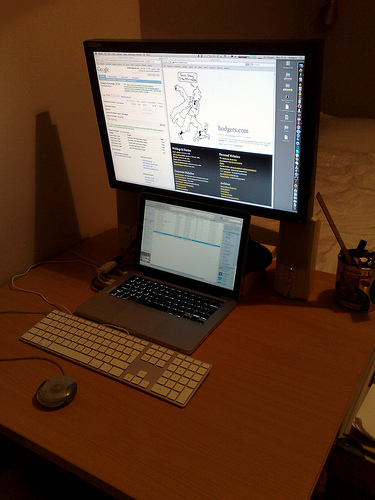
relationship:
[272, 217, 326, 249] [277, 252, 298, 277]
speaker with light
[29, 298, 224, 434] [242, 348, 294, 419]
flat keyboard desk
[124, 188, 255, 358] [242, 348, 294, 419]
laptop on desk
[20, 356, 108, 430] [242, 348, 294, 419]
mouse on desk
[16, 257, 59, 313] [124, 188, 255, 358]
cord by laptop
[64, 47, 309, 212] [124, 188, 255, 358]
screen for computer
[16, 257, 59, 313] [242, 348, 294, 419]
cord on desk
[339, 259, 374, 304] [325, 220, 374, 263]
cup with pencils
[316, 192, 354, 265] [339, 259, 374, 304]
pencils in cup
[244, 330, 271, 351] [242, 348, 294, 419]
brown wood desk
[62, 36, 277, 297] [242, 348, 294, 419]
computer on desk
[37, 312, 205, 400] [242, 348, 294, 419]
keyboard on desk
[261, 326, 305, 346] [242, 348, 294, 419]
wooden computer desk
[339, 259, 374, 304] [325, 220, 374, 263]
cup holding pencils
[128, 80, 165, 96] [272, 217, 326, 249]
white computer speaker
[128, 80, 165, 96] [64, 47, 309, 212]
white paper screen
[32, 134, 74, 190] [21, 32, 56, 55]
shadow on wall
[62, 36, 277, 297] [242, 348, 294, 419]
computer mouse desk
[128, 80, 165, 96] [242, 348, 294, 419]
white keyboard desk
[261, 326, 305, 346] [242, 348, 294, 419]
wooden brown desk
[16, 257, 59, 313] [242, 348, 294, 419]
cords on desk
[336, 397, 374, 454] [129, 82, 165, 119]
pile of paper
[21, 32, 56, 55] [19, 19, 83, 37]
wall painted tan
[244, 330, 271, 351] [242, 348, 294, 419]
brown top desk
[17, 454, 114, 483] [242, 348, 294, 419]
edge of desk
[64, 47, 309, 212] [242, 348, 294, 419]
screen on desk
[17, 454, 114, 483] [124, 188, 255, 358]
edge of laptop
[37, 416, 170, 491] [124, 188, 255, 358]
table has laptop